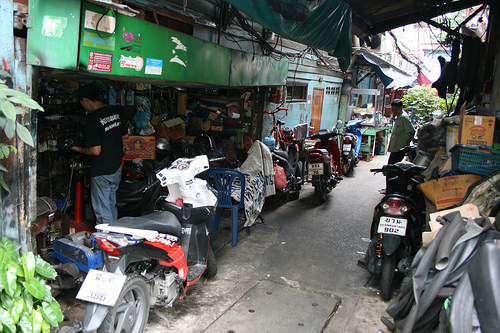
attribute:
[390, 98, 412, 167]
man — standing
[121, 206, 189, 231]
seat — black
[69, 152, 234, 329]
scooter — red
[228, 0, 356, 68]
green tarp — hanging, overhead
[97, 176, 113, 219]
jeans — blue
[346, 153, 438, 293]
scooter — blue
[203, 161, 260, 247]
chair — blue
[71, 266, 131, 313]
license plate — white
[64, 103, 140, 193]
shirt — a black 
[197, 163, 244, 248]
blue chair — dark, plastic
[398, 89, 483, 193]
table — light blue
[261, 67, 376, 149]
wall — green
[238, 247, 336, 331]
cement — plate, holes 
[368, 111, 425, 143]
shirt — green 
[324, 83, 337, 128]
wall — blue 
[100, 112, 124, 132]
writing — White 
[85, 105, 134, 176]
shirt —  black 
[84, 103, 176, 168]
shirt — black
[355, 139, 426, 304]
motorcycle — black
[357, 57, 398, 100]
tarp canopy — blue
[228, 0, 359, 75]
tarp — green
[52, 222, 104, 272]
hamper — Blue plastic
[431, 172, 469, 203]
box — cardboard 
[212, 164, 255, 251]
chair — plastic